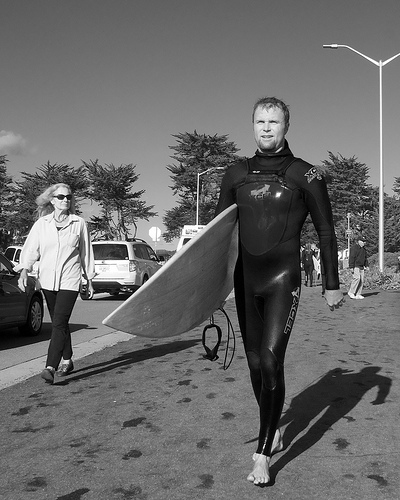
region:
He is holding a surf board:
[96, 89, 368, 439]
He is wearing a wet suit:
[209, 83, 357, 492]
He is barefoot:
[221, 403, 320, 499]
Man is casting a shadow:
[227, 336, 395, 498]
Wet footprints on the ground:
[3, 283, 398, 497]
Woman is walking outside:
[7, 173, 106, 393]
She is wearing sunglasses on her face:
[29, 175, 86, 235]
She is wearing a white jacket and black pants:
[7, 169, 107, 392]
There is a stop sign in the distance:
[139, 217, 168, 268]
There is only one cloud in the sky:
[0, 44, 214, 162]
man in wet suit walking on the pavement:
[214, 95, 346, 487]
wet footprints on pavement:
[118, 368, 246, 497]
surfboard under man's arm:
[100, 203, 238, 340]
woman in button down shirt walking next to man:
[10, 180, 94, 381]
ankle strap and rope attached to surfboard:
[200, 308, 237, 372]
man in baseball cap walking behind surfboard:
[346, 236, 368, 300]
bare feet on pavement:
[246, 428, 283, 485]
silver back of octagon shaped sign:
[146, 225, 162, 240]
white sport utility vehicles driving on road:
[77, 236, 162, 296]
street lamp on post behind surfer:
[194, 163, 226, 236]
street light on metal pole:
[318, 38, 398, 275]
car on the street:
[77, 235, 168, 301]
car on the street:
[0, 235, 46, 350]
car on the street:
[0, 241, 40, 278]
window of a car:
[88, 241, 131, 262]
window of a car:
[133, 242, 159, 261]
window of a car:
[4, 246, 16, 259]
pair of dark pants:
[38, 277, 85, 368]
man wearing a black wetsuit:
[209, 96, 346, 485]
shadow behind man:
[243, 365, 396, 486]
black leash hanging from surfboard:
[201, 305, 235, 367]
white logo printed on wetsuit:
[282, 287, 303, 335]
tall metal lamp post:
[323, 39, 399, 273]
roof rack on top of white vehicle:
[77, 237, 165, 299]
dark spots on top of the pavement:
[196, 472, 216, 490]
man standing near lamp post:
[346, 235, 371, 300]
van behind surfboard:
[175, 224, 210, 251]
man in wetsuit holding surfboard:
[100, 98, 347, 486]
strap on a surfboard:
[200, 309, 237, 374]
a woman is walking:
[13, 183, 95, 389]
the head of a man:
[249, 94, 289, 152]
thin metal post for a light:
[378, 58, 384, 279]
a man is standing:
[347, 234, 369, 303]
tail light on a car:
[129, 259, 138, 272]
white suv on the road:
[79, 235, 165, 300]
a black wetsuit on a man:
[215, 149, 345, 453]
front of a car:
[0, 250, 44, 340]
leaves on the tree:
[171, 129, 213, 181]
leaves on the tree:
[98, 179, 130, 205]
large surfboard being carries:
[103, 203, 241, 340]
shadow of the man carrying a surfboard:
[249, 364, 390, 484]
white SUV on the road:
[90, 239, 163, 293]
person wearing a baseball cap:
[348, 234, 368, 300]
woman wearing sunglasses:
[18, 181, 96, 382]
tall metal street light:
[320, 41, 397, 275]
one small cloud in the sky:
[2, 129, 39, 157]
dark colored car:
[2, 252, 44, 337]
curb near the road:
[1, 328, 131, 392]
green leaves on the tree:
[339, 151, 359, 182]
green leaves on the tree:
[368, 210, 373, 246]